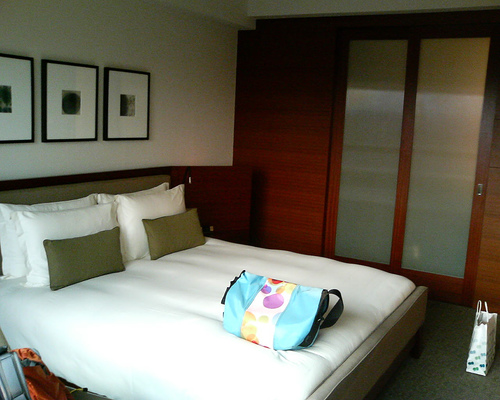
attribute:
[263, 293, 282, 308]
circle — Purple 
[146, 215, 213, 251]
pillow — Green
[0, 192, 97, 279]
pillow — white 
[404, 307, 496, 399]
carpet — grey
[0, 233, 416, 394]
sheets — white 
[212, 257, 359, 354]
bag — White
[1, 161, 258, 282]
headboard — red , wood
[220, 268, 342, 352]
tote bag — white 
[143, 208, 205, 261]
pillow — green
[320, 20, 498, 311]
doors — opaque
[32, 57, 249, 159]
photos — white 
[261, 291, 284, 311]
circle — small, purple, decoration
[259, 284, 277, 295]
circle — small, purple, decoration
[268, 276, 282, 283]
circle — small, purple, decoration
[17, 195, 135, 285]
pillow — White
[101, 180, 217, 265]
pillow — White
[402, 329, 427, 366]
foot — black